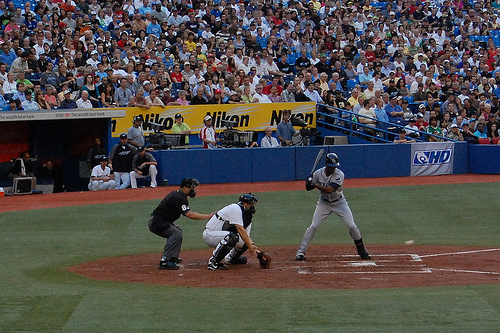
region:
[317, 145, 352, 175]
head of a person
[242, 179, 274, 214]
head of a person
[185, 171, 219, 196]
head of a person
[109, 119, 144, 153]
head of a person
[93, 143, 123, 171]
head of a person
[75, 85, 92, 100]
head of a person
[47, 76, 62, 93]
head of a person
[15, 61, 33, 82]
head of a person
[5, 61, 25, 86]
head of a person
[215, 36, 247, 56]
head of a person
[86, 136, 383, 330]
men on the baseball field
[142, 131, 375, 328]
men on a field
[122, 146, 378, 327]
baseball players on a baseball field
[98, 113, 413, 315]
players on a field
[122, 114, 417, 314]
men playing baseball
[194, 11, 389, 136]
people sitting in a standium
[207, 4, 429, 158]
people watching a baseball game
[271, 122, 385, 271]
a man holding a bat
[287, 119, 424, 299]
a man wearing a helmet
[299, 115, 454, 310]
a man swinging a bat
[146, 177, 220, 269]
umpire officiates the game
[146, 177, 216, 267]
umpire gets ready to make the call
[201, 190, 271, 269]
player tries to catch the ball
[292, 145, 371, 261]
player decides not to swing at the ball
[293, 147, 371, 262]
human holds a bat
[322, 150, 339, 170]
helmet is worn by human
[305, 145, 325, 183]
bat is held by human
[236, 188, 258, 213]
helmet is worn by human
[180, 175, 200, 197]
mask is worn by human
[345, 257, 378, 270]
home plate has dirt on it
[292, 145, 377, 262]
Batter ready to hit a ball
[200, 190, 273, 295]
Catcher waiting on the pitcher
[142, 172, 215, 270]
Umpire waiting for a pitch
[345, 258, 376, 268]
Home Plate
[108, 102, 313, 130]
Yellow sign advertising Nikon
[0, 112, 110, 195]
The baseball team's dugout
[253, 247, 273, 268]
A baseball glove belonging to the catcher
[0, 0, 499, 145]
Baseball fans in the stands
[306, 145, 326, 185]
A baseball bat being held by the batter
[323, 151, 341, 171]
A Batting helmet worn by the batter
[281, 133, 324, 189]
The man is holding a bat.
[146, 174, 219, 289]
The umpire is behind the catcher.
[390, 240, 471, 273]
White lines in the field.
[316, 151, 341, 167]
The player is wearing a helmet.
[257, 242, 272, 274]
The catcher has gloves in hand.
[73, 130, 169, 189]
Players standing by the wall.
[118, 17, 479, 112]
People in the bleachers.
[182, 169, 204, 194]
The umpire is wearing a face mask.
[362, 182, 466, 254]
The field is green.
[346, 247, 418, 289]
The player is standing by home plate.